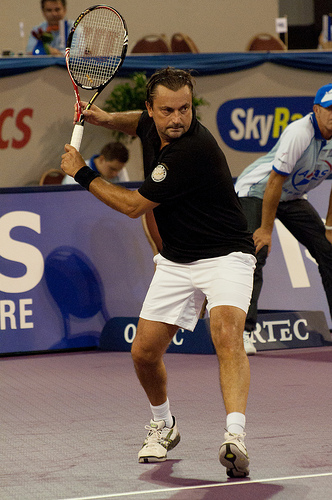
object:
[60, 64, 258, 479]
man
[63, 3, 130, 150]
racket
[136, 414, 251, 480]
shoes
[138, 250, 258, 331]
shorts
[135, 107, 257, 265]
shirt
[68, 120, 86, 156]
handle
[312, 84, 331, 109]
hat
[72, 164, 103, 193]
wristband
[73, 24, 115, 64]
w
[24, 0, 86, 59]
man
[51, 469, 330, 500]
line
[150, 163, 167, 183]
logo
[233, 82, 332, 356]
man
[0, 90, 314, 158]
advertisement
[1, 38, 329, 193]
wall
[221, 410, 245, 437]
sock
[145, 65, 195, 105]
hair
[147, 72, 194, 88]
headband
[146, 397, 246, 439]
socks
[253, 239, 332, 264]
knees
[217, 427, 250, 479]
foot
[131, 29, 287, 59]
chairs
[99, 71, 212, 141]
plant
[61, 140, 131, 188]
man